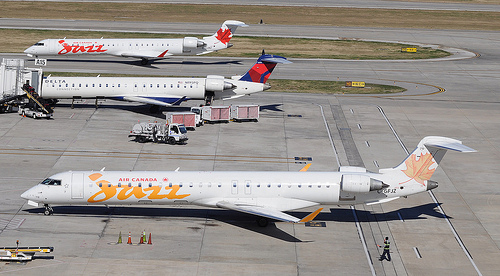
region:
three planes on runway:
[11, 13, 478, 233]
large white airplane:
[19, 130, 475, 242]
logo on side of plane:
[84, 171, 189, 205]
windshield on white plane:
[39, 178, 62, 186]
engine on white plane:
[339, 171, 388, 195]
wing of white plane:
[217, 193, 304, 228]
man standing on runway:
[379, 232, 399, 262]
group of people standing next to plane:
[114, 230, 161, 247]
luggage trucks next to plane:
[133, 99, 263, 146]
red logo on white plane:
[59, 39, 110, 57]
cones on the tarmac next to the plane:
[106, 225, 156, 248]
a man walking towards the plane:
[377, 232, 394, 266]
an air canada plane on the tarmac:
[13, 133, 481, 230]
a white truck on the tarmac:
[124, 119, 190, 146]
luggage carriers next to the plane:
[156, 100, 265, 130]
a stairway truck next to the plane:
[13, 80, 59, 121]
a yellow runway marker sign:
[340, 73, 367, 91]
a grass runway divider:
[3, 25, 458, 63]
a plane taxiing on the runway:
[21, 16, 248, 68]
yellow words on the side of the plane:
[82, 172, 195, 204]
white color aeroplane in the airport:
[22, 135, 477, 232]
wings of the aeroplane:
[218, 195, 312, 227]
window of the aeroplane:
[118, 175, 330, 192]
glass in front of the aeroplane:
[38, 173, 67, 188]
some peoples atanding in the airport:
[112, 225, 162, 249]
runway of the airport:
[282, 25, 498, 135]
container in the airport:
[128, 100, 265, 140]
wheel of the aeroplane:
[36, 205, 60, 218]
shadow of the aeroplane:
[341, 204, 451, 227]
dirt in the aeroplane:
[288, 8, 492, 28]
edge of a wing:
[268, 213, 285, 225]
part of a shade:
[268, 229, 290, 251]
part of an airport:
[207, 215, 227, 232]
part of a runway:
[209, 256, 226, 271]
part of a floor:
[196, 217, 228, 253]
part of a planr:
[157, 188, 196, 227]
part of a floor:
[220, 253, 237, 273]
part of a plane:
[187, 175, 198, 183]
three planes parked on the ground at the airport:
[19, 13, 483, 270]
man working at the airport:
[367, 226, 400, 266]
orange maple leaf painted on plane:
[399, 147, 437, 189]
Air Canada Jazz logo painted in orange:
[86, 167, 193, 210]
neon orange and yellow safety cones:
[112, 222, 161, 249]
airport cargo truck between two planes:
[119, 95, 191, 145]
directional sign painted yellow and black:
[341, 71, 372, 90]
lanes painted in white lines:
[312, 88, 402, 158]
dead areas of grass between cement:
[280, 32, 335, 54]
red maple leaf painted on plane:
[212, 24, 236, 46]